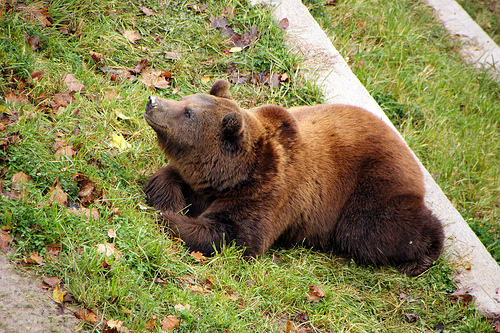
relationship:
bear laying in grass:
[145, 86, 493, 261] [34, 16, 286, 157]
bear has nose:
[143, 79, 444, 277] [141, 90, 159, 110]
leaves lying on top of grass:
[113, 65, 173, 85] [410, 54, 465, 141]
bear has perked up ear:
[143, 79, 444, 277] [209, 78, 235, 101]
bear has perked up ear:
[143, 79, 444, 277] [220, 109, 244, 137]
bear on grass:
[143, 79, 444, 277] [0, 1, 498, 331]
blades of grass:
[209, 230, 248, 272] [0, 1, 498, 331]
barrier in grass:
[253, 0, 378, 107] [0, 1, 498, 331]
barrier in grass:
[421, 0, 498, 96] [0, 1, 498, 331]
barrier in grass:
[421, 157, 497, 332] [0, 1, 498, 331]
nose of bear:
[138, 87, 163, 132] [143, 79, 444, 277]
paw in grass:
[150, 207, 188, 236] [0, 1, 498, 331]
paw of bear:
[149, 200, 237, 268] [141, 67, 413, 229]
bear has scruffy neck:
[143, 79, 444, 277] [219, 96, 304, 200]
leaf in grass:
[58, 72, 88, 96] [5, 60, 157, 218]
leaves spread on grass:
[67, 157, 117, 242] [0, 1, 498, 331]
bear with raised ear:
[143, 79, 444, 277] [218, 109, 243, 148]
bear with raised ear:
[143, 79, 444, 277] [208, 76, 233, 99]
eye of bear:
[178, 98, 203, 125] [143, 79, 444, 277]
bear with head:
[143, 79, 444, 277] [146, 78, 255, 188]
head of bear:
[132, 79, 266, 188] [143, 79, 444, 277]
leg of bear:
[155, 194, 289, 260] [143, 79, 444, 277]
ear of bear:
[219, 112, 241, 139] [128, 74, 441, 271]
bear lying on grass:
[143, 79, 444, 277] [9, 25, 497, 325]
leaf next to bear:
[189, 248, 206, 265] [143, 79, 444, 277]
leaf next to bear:
[65, 62, 87, 96] [171, 72, 469, 287]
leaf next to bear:
[70, 162, 110, 218] [128, 82, 467, 295]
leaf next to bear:
[39, 176, 69, 209] [143, 79, 444, 277]